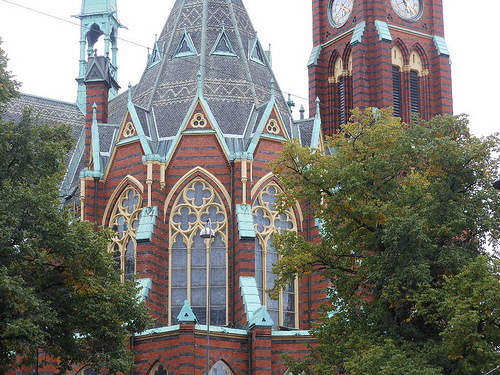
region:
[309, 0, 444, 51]
a double sided clock tower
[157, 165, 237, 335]
an arched window on a church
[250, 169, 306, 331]
an arched window on a church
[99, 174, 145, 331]
an arched window on a church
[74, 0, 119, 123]
a tower on the roof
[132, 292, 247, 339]
a balcony outside the window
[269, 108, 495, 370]
tree in front of the church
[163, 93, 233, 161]
light green trim on roof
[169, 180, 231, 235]
three circles on the window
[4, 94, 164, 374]
tree in front of the church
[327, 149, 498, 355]
The tree is tall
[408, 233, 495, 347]
The leaves are green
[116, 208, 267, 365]
The building is made of brick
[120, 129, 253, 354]
The windows are arched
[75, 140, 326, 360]
The building has 3 front windows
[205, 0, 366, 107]
The sky is white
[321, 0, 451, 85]
The building has 2 clocks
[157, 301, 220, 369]
The building is red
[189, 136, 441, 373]
The tree is in front of the building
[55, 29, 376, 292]
The building's roof is steep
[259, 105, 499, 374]
Large green leafy tree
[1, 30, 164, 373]
Large green leafy tree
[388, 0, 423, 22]
Clock with a white face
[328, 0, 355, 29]
Clock with a white face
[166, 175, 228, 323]
Large window with a golden design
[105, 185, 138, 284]
Large window with golden design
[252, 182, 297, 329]
Large window with golden design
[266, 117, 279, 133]
Three small windows with golden trim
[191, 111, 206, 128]
Three small windows with golden trim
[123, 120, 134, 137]
Three small windows with golden trim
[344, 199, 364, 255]
the trees are visible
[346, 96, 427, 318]
the trees are visible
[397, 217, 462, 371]
the trees are visible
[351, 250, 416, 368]
the trees are visible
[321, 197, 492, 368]
the trees are visible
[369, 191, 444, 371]
the trees are visible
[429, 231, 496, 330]
the trees are visible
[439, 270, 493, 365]
the trees are visible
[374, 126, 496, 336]
the trees are visible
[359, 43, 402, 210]
the trees are visible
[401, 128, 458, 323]
the trees are visible